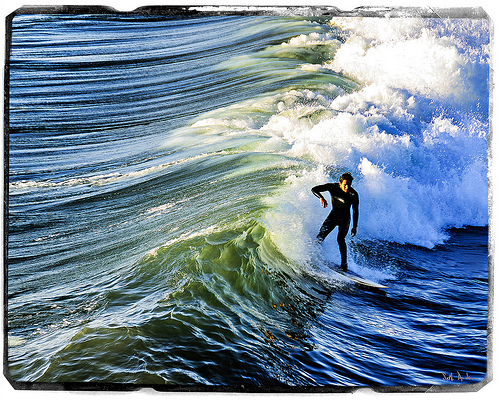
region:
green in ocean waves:
[177, 0, 352, 307]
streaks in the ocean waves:
[11, 10, 232, 309]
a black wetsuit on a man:
[312, 182, 361, 269]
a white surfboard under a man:
[313, 244, 383, 296]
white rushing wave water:
[274, 5, 495, 261]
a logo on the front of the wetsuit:
[333, 193, 348, 205]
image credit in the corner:
[439, 370, 477, 384]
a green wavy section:
[170, 228, 266, 299]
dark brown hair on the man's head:
[335, 168, 353, 187]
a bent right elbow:
[309, 185, 319, 193]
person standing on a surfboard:
[288, 166, 397, 301]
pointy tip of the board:
[365, 278, 397, 296]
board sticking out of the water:
[296, 248, 401, 300]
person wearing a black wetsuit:
[306, 176, 358, 270]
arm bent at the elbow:
[310, 180, 335, 210]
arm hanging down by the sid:
[348, 193, 363, 240]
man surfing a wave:
[102, 8, 489, 398]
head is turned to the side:
[338, 172, 353, 197]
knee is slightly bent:
[333, 232, 350, 249]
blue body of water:
[12, 10, 489, 389]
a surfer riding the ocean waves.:
[313, 170, 388, 303]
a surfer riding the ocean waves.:
[306, 166, 386, 301]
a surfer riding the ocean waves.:
[310, 166, 386, 296]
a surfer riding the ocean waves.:
[305, 167, 393, 302]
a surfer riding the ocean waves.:
[303, 165, 390, 297]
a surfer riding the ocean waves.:
[308, 168, 389, 292]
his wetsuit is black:
[314, 175, 374, 252]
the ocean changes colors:
[12, 105, 454, 389]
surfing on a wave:
[272, 208, 380, 290]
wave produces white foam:
[331, 41, 464, 196]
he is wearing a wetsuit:
[303, 169, 365, 266]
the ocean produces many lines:
[45, 20, 178, 322]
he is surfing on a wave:
[287, 160, 368, 311]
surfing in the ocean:
[248, 125, 402, 314]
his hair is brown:
[337, 153, 364, 186]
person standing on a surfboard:
[297, 172, 401, 314]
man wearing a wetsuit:
[305, 174, 365, 271]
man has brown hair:
[331, 162, 353, 187]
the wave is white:
[323, 45, 474, 323]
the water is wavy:
[168, 6, 473, 339]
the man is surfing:
[296, 151, 403, 361]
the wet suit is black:
[302, 172, 388, 279]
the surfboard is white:
[311, 245, 409, 308]